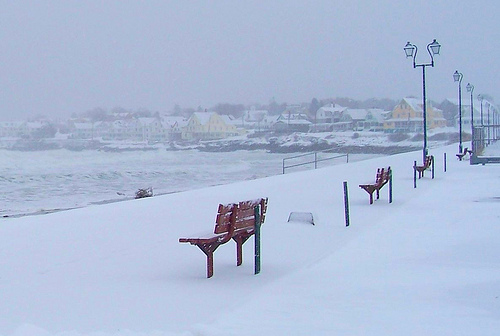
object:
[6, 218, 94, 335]
snow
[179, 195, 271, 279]
bench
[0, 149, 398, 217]
water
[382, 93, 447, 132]
house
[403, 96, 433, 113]
snow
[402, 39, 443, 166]
lampost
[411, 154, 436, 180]
bench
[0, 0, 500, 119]
sky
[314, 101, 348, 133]
building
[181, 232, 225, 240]
snow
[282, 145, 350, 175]
rail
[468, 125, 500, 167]
fence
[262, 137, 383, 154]
rocks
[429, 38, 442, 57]
lights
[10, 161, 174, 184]
sow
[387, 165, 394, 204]
pole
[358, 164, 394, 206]
bench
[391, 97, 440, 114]
roof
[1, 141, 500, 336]
walkway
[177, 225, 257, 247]
seat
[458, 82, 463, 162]
post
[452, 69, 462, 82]
light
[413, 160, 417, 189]
poles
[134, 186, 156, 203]
object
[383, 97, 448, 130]
orage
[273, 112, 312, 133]
houses